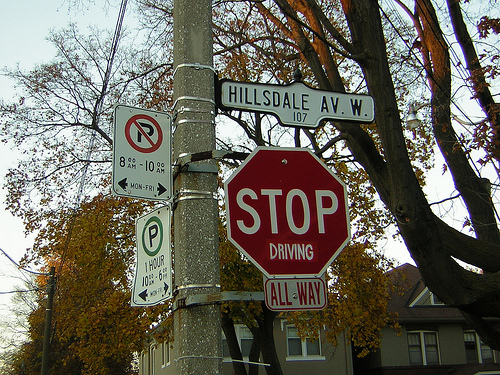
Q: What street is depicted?
A: Hillsdale Av. W.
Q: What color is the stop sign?
A: Red.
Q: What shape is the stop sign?
A: Octagonal.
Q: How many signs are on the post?
A: Five.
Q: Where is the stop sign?
A: Below the street sign.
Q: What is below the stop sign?
A: An "ALL WAY" sign.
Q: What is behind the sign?
A: A house.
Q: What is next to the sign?
A: A tree.